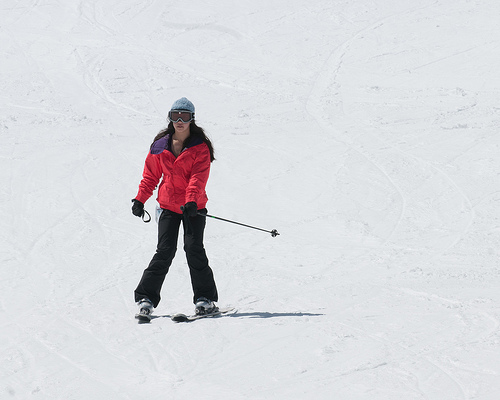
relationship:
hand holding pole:
[177, 199, 199, 216] [179, 205, 281, 238]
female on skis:
[129, 93, 222, 320] [119, 305, 228, 326]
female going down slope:
[129, 93, 222, 320] [0, 0, 494, 396]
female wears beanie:
[129, 93, 222, 320] [169, 97, 194, 122]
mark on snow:
[301, 6, 408, 251] [1, 0, 497, 398]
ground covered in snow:
[2, 2, 485, 396] [388, 107, 408, 149]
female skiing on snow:
[129, 93, 222, 320] [1, 0, 497, 398]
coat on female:
[137, 128, 221, 211] [129, 93, 222, 320]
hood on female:
[142, 132, 202, 149] [129, 93, 222, 320]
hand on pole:
[177, 199, 199, 216] [179, 205, 281, 238]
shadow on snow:
[215, 304, 325, 321] [323, 349, 370, 379]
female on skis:
[129, 93, 222, 320] [173, 306, 238, 322]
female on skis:
[129, 93, 222, 320] [135, 309, 153, 323]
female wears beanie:
[129, 93, 222, 320] [171, 95, 194, 116]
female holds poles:
[129, 93, 222, 320] [135, 201, 286, 243]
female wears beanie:
[129, 93, 222, 320] [173, 99, 195, 114]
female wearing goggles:
[129, 93, 222, 320] [158, 108, 200, 126]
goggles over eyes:
[158, 108, 200, 126] [153, 109, 212, 128]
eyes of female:
[153, 109, 212, 128] [129, 93, 222, 320]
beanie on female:
[171, 95, 196, 114] [129, 93, 222, 320]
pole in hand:
[179, 205, 281, 238] [180, 201, 198, 216]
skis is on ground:
[173, 306, 238, 322] [2, 2, 485, 396]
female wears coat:
[129, 93, 222, 320] [137, 128, 221, 211]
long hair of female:
[186, 120, 216, 167] [129, 93, 222, 320]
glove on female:
[115, 196, 158, 222] [129, 93, 222, 320]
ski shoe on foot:
[193, 294, 221, 314] [190, 294, 216, 316]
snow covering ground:
[316, 16, 498, 370] [2, 2, 485, 396]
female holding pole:
[129, 93, 222, 320] [179, 205, 281, 238]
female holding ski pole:
[129, 93, 222, 320] [131, 197, 153, 225]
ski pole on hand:
[118, 192, 151, 222] [86, 125, 168, 223]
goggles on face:
[158, 108, 200, 126] [167, 105, 192, 137]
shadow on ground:
[215, 304, 325, 321] [2, 2, 485, 396]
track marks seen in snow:
[252, 6, 494, 397] [237, 87, 487, 321]